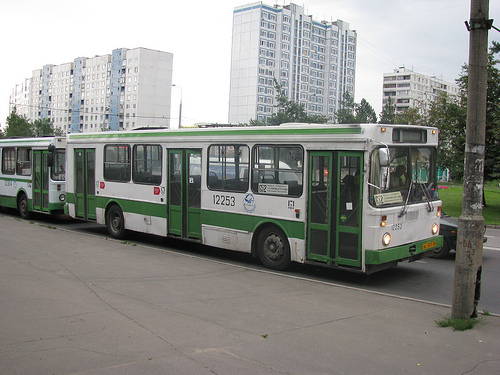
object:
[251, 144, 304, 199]
window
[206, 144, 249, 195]
window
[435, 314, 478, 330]
grass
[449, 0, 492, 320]
pole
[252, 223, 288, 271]
tire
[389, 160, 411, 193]
bus driver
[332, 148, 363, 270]
doors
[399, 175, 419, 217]
windshield wiper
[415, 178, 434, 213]
windshield wiper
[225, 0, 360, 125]
building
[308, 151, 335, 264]
door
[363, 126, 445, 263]
front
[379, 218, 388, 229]
lights on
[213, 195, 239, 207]
12253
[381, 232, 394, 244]
headlight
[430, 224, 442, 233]
headlight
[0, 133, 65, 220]
bus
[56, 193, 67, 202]
headlight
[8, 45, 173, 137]
building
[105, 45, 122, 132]
stripes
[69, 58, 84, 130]
stripes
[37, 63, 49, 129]
stripes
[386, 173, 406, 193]
seat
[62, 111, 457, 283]
bus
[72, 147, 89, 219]
door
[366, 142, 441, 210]
windshield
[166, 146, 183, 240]
door